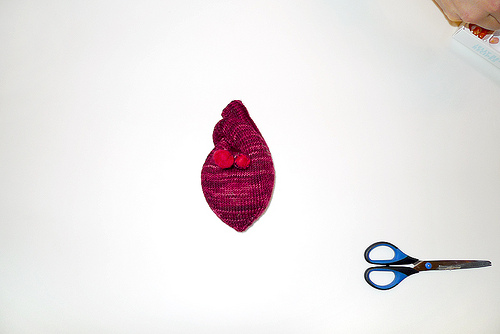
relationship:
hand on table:
[434, 0, 499, 44] [2, 1, 499, 333]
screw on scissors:
[423, 261, 435, 270] [364, 241, 496, 291]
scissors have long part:
[364, 241, 496, 291] [430, 259, 493, 270]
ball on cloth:
[211, 148, 236, 169] [201, 100, 276, 233]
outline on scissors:
[364, 241, 419, 290] [364, 241, 496, 291]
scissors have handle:
[364, 241, 496, 291] [364, 241, 416, 291]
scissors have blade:
[364, 241, 496, 291] [433, 259, 492, 272]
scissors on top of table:
[364, 241, 496, 291] [2, 1, 499, 333]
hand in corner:
[434, 0, 499, 44] [414, 2, 500, 85]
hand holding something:
[434, 0, 499, 44] [452, 22, 499, 71]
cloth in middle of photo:
[201, 100, 276, 233] [2, 1, 499, 333]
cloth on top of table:
[201, 100, 276, 233] [2, 1, 499, 333]